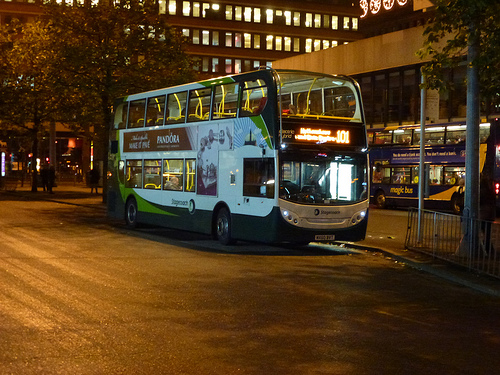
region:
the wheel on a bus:
[187, 195, 271, 260]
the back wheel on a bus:
[111, 180, 166, 242]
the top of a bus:
[113, 58, 310, 137]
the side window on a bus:
[105, 138, 240, 191]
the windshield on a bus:
[241, 143, 384, 244]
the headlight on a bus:
[263, 191, 407, 245]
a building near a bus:
[140, 5, 281, 117]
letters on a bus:
[286, 110, 387, 150]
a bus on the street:
[53, 69, 362, 277]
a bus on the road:
[46, 19, 359, 300]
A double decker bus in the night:
[102, 62, 372, 258]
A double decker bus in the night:
[98, 65, 371, 251]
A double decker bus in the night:
[98, 65, 370, 257]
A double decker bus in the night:
[96, 61, 371, 256]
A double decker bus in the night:
[95, 66, 381, 257]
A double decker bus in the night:
[101, 65, 376, 256]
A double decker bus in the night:
[100, 60, 376, 260]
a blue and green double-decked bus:
[105, 62, 372, 246]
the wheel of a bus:
[122, 196, 139, 228]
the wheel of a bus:
[210, 203, 233, 244]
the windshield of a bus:
[277, 156, 371, 208]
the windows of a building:
[220, 4, 275, 25]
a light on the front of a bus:
[279, 206, 291, 221]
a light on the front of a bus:
[278, 142, 288, 152]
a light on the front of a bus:
[356, 207, 368, 222]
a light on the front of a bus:
[359, 144, 369, 156]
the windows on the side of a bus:
[122, 155, 199, 192]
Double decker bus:
[105, 67, 370, 247]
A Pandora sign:
[123, 120, 233, 197]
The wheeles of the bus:
[123, 192, 230, 244]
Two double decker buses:
[105, 67, 496, 248]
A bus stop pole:
[414, 65, 442, 261]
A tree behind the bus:
[1, 3, 202, 207]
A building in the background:
[2, 0, 388, 81]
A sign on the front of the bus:
[278, 115, 368, 149]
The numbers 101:
[335, 128, 350, 144]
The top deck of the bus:
[111, 66, 365, 131]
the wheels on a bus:
[193, 185, 263, 248]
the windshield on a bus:
[256, 133, 386, 222]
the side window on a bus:
[208, 143, 297, 220]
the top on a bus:
[125, 43, 287, 147]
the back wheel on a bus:
[106, 185, 163, 255]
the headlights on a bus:
[264, 167, 419, 238]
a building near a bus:
[141, 6, 326, 121]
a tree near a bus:
[33, 17, 225, 137]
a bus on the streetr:
[55, 65, 383, 292]